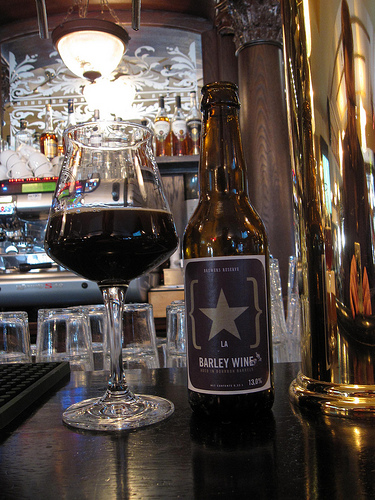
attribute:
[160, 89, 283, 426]
bottle — brown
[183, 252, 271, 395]
label — brown, white 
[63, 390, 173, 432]
base — round 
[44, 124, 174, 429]
glass — wine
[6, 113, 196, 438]
glass — large clear 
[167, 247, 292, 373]
bottle wine — wine , small 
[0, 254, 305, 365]
glasses — small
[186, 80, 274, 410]
bottle —  wine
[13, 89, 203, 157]
bottles — booze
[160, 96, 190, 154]
bottles — liquor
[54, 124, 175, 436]
glass — wine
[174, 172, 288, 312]
glass — wine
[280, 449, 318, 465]
bottle —  wine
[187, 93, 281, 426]
bottle — small, wine 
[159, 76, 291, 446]
bottle — wine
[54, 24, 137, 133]
light — white 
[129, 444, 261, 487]
table — black 